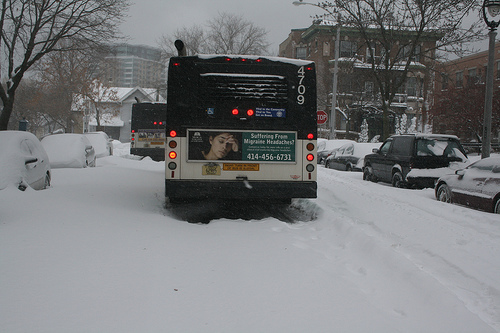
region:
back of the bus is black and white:
[189, 64, 269, 179]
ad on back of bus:
[186, 130, 323, 164]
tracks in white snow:
[194, 215, 369, 299]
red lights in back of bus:
[226, 90, 273, 128]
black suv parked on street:
[373, 126, 415, 186]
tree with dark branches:
[367, 61, 425, 116]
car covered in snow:
[0, 130, 56, 228]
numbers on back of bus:
[290, 69, 305, 125]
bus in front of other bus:
[128, 74, 162, 166]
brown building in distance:
[460, 104, 477, 125]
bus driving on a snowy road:
[141, 25, 347, 296]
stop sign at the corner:
[315, 100, 332, 129]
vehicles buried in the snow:
[5, 119, 96, 215]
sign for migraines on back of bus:
[183, 125, 300, 166]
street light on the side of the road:
[475, 1, 498, 165]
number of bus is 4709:
[290, 60, 311, 114]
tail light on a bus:
[167, 127, 182, 172]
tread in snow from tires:
[347, 202, 477, 299]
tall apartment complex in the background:
[66, 25, 164, 101]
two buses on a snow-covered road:
[128, 37, 328, 213]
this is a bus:
[153, 29, 353, 236]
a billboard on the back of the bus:
[178, 125, 303, 176]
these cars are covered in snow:
[5, 114, 129, 213]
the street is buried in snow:
[4, 148, 496, 324]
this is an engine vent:
[187, 65, 303, 118]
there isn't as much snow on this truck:
[344, 130, 465, 192]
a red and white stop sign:
[306, 98, 338, 125]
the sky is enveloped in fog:
[5, 3, 491, 78]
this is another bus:
[105, 76, 180, 167]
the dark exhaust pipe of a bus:
[167, 28, 200, 60]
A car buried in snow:
[38, 133, 103, 176]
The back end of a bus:
[168, 38, 318, 208]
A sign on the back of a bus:
[188, 127, 300, 164]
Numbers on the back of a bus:
[291, 62, 312, 105]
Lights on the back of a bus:
[225, 103, 255, 117]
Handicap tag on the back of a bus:
[205, 103, 215, 120]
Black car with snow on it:
[363, 128, 471, 199]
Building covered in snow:
[310, 21, 437, 141]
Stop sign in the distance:
[314, 105, 326, 127]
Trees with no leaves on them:
[8, 15, 135, 112]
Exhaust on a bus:
[170, 39, 187, 55]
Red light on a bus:
[169, 129, 177, 138]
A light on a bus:
[167, 161, 177, 171]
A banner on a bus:
[185, 128, 300, 163]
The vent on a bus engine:
[195, 71, 290, 106]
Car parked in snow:
[40, 132, 96, 168]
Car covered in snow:
[82, 128, 111, 158]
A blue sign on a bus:
[256, 107, 286, 118]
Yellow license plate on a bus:
[221, 163, 259, 173]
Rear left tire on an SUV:
[389, 171, 403, 188]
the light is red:
[231, 106, 239, 114]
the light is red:
[245, 109, 252, 114]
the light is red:
[307, 133, 314, 140]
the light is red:
[306, 153, 312, 160]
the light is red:
[170, 130, 179, 137]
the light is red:
[167, 150, 176, 160]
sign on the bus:
[187, 129, 297, 164]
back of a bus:
[131, 101, 167, 157]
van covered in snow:
[0, 129, 48, 196]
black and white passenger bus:
[146, 42, 327, 227]